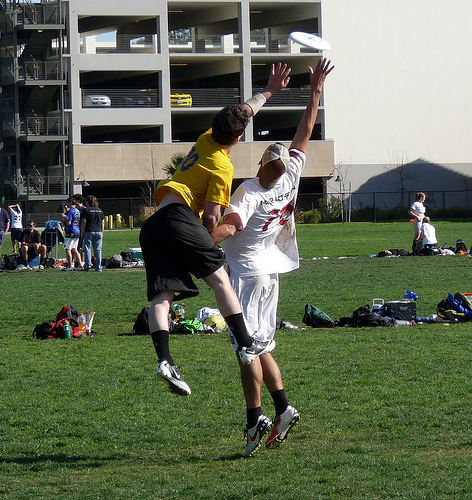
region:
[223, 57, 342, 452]
man in a white shirt jumping in the air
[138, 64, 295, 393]
man in a yellow shirt jumping in the air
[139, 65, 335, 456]
two men jumping for the frisbee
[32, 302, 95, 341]
orange backpack in the open field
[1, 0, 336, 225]
parking garage next to the field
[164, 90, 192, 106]
yellow car on the second floor of the parking garage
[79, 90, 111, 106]
white car on the second floor of the garage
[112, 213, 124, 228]
yellow fire hydrant next to the parking garage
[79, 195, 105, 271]
man in a black shirt and jeans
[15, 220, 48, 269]
man in a black shirt sitting down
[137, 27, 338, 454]
two men reaching for a frisbee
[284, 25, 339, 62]
a white frisbee in midair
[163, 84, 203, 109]
yellow car in a parking garage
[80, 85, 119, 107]
silver car in a parking garage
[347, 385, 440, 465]
green gras of the field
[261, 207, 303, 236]
red numbers on a white shirt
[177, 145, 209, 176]
blue numders on a yellow shirt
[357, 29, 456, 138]
cloudy grey skies over the field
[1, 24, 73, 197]
stairs of the parking garage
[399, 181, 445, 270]
two people wearing white in the background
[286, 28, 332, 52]
A white frisbee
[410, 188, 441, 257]
Two people in white shirts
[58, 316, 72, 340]
A green water bottle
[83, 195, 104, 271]
A person in a black shirt and jeans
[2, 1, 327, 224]
A multistory parking garage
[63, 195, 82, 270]
A person in a blue shirt and white shorts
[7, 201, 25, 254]
A person with their hands on the back of their head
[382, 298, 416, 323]
A black milk crate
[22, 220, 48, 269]
sitting guy in a black shirt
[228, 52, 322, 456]
A guy dressed in white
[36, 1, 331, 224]
gray concrete parking garage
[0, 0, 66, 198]
metal stairs attached to parking garage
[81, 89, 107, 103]
white car parked in parking garage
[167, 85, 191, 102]
yellow sports car parked in parking garage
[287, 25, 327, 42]
round white frisbee mid air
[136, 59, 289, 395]
man jumping to catch frisbee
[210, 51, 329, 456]
man reaching to grab frisbee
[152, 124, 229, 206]
yellow tshirt on man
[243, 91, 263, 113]
white arm band on man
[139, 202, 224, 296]
black shorts on man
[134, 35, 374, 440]
the men are playing frisbee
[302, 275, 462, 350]
bags on the ground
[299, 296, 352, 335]
bags on the ground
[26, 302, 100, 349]
bags on the ground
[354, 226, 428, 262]
bags on the ground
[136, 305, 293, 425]
the socks are black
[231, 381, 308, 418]
the socks are black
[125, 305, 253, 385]
the socks are black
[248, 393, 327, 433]
the socks are black